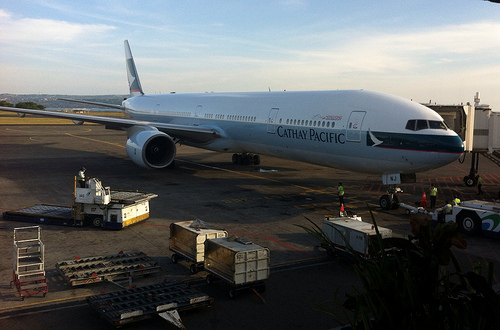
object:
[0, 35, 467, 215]
plane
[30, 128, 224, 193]
tarmac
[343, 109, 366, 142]
door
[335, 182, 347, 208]
workers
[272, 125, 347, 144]
name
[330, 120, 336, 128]
windows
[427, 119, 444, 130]
windshield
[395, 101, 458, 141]
cockpit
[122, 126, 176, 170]
engine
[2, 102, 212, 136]
wing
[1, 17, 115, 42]
cloud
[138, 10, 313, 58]
sky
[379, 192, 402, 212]
wheels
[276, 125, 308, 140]
cathay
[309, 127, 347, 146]
pacific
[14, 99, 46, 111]
tree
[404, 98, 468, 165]
front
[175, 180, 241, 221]
pavement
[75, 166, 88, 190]
man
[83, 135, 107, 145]
line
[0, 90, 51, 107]
hills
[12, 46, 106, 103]
background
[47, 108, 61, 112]
water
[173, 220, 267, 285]
crates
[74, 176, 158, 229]
vehicle